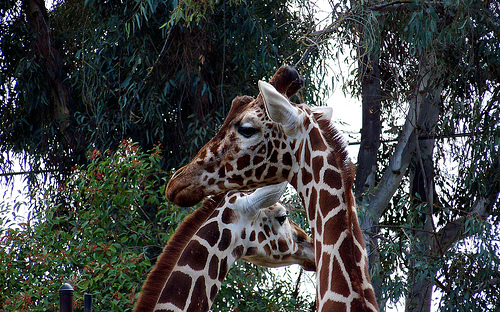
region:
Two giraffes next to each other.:
[167, 72, 364, 296]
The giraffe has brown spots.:
[294, 139, 350, 263]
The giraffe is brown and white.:
[149, 153, 376, 286]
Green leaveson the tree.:
[74, 15, 225, 114]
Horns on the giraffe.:
[263, 55, 303, 88]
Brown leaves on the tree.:
[47, 208, 146, 280]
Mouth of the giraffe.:
[159, 163, 203, 215]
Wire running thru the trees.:
[19, 120, 490, 147]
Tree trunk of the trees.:
[368, 82, 445, 297]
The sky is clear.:
[212, 15, 393, 115]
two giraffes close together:
[144, 54, 362, 305]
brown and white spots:
[297, 157, 348, 304]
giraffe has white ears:
[270, 73, 310, 133]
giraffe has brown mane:
[134, 178, 208, 288]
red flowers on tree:
[22, 145, 169, 302]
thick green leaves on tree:
[42, 0, 363, 125]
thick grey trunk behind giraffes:
[314, 64, 471, 304]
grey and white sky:
[300, 18, 378, 125]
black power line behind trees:
[332, 127, 497, 172]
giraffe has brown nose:
[174, 141, 212, 203]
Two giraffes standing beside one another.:
[135, 64, 370, 308]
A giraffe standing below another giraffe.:
[136, 186, 313, 310]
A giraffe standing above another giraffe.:
[166, 62, 377, 310]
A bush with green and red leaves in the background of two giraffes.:
[1, 143, 163, 308]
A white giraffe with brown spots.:
[168, 63, 374, 307]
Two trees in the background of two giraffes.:
[336, 1, 493, 306]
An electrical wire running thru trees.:
[345, 128, 497, 144]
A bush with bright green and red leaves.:
[0, 142, 164, 307]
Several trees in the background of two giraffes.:
[1, 1, 211, 146]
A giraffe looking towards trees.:
[136, 182, 307, 306]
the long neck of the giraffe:
[137, 204, 233, 309]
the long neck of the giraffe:
[297, 123, 367, 309]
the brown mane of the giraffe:
[312, 110, 363, 245]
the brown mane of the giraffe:
[137, 188, 216, 310]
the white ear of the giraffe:
[243, 176, 283, 208]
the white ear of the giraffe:
[260, 79, 295, 121]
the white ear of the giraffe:
[315, 100, 338, 124]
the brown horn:
[260, 62, 293, 104]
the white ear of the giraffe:
[286, 75, 304, 100]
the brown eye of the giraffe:
[275, 208, 287, 225]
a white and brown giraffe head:
[155, 70, 355, 197]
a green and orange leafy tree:
[5, 148, 140, 295]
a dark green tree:
[3, 3, 220, 133]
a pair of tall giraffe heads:
[131, 63, 381, 310]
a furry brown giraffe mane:
[317, 113, 359, 216]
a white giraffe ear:
[256, 76, 304, 133]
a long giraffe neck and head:
[165, 69, 383, 310]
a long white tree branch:
[403, 2, 496, 309]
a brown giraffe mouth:
[161, 168, 201, 206]